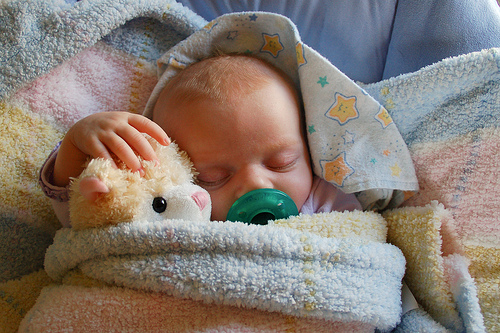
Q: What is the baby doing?
A: Sleeping.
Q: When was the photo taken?
A: Day time.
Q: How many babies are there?
A: One.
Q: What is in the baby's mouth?
A: A pacifier.